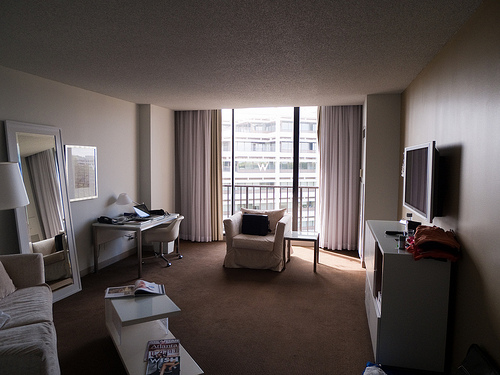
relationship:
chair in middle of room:
[222, 207, 291, 272] [1, 0, 498, 373]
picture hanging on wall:
[64, 146, 100, 201] [64, 86, 141, 278]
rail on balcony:
[222, 185, 319, 191] [222, 185, 319, 214]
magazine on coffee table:
[105, 280, 167, 298] [104, 288, 205, 373]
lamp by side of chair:
[1, 162, 30, 213] [2, 255, 62, 374]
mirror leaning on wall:
[6, 121, 83, 297] [64, 86, 141, 278]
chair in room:
[2, 255, 62, 374] [1, 0, 498, 373]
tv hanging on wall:
[403, 141, 435, 224] [64, 86, 141, 278]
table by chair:
[280, 231, 320, 272] [222, 207, 291, 272]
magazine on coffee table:
[146, 341, 178, 375] [104, 288, 205, 373]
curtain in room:
[177, 111, 223, 243] [1, 0, 498, 373]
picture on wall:
[64, 146, 100, 201] [64, 86, 141, 278]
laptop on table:
[134, 202, 164, 222] [92, 215, 176, 280]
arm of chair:
[224, 210, 242, 236] [222, 207, 291, 272]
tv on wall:
[403, 141, 435, 224] [64, 86, 141, 278]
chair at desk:
[144, 215, 181, 268] [92, 215, 176, 280]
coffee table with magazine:
[104, 288, 205, 373] [146, 341, 178, 375]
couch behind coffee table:
[2, 255, 62, 374] [104, 288, 205, 373]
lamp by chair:
[1, 162, 30, 213] [2, 255, 62, 374]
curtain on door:
[316, 107, 358, 251] [227, 106, 318, 208]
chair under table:
[144, 215, 181, 268] [92, 215, 176, 280]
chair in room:
[222, 207, 291, 272] [1, 0, 498, 373]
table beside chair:
[280, 231, 320, 272] [222, 207, 291, 272]